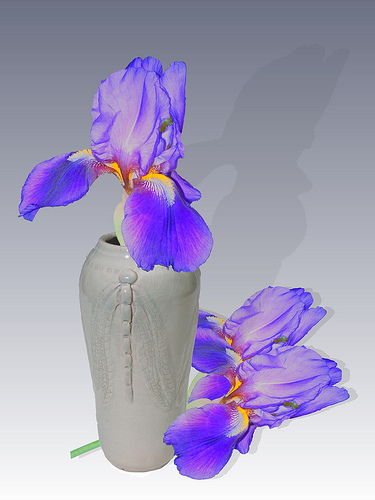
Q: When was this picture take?
A: After the flowers were picked.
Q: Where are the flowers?
A: In and around the vase.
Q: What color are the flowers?
A: Purple and yellow.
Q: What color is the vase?
A: Grey.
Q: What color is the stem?
A: Green.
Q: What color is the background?
A: Grey and white.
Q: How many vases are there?
A: One.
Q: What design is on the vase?
A: A dragonfly.